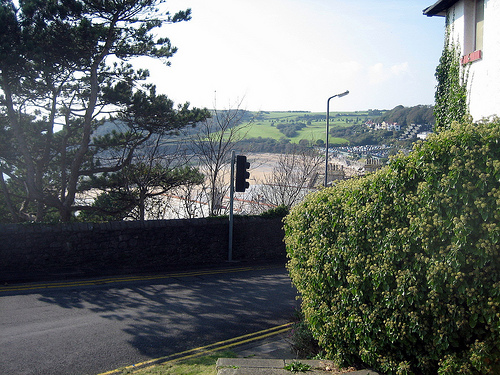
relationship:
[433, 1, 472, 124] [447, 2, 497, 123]
vines in wall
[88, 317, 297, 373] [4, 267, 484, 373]
line on road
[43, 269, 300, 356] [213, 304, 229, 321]
shadow has part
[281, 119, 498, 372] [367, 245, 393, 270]
bush has part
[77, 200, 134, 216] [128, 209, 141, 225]
branch has part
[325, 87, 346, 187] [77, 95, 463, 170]
post on background